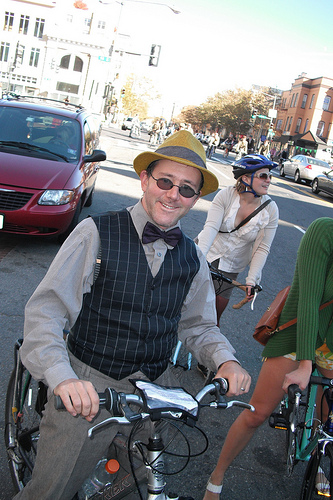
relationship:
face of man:
[140, 160, 201, 226] [29, 128, 255, 499]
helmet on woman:
[233, 154, 278, 183] [196, 152, 286, 326]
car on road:
[261, 109, 328, 206] [117, 105, 316, 377]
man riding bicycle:
[29, 128, 255, 499] [0, 319, 256, 496]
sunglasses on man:
[145, 167, 199, 197] [8, 129, 243, 499]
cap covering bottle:
[105, 459, 120, 474] [71, 458, 120, 500]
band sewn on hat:
[153, 144, 208, 170] [118, 102, 264, 203]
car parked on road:
[281, 155, 329, 193] [1, 123, 323, 497]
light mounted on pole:
[249, 87, 257, 97] [260, 91, 278, 158]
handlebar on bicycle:
[202, 370, 249, 417] [107, 371, 197, 489]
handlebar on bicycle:
[96, 383, 135, 414] [107, 371, 197, 489]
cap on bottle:
[104, 459, 120, 473] [76, 455, 120, 499]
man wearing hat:
[29, 128, 255, 499] [127, 126, 220, 200]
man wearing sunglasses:
[29, 128, 255, 499] [146, 167, 201, 200]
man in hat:
[29, 128, 255, 499] [132, 128, 220, 197]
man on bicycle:
[29, 128, 255, 499] [0, 337, 255, 500]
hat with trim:
[132, 128, 220, 197] [151, 146, 208, 172]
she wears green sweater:
[202, 216, 331, 498] [261, 215, 333, 363]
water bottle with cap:
[66, 440, 134, 499] [98, 449, 128, 477]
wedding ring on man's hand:
[238, 382, 248, 395] [227, 363, 254, 401]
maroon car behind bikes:
[0, 98, 105, 235] [82, 374, 188, 497]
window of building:
[308, 93, 317, 108] [271, 70, 332, 164]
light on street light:
[251, 115, 256, 119] [249, 107, 256, 124]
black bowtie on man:
[142, 221, 181, 248] [18, 118, 226, 417]